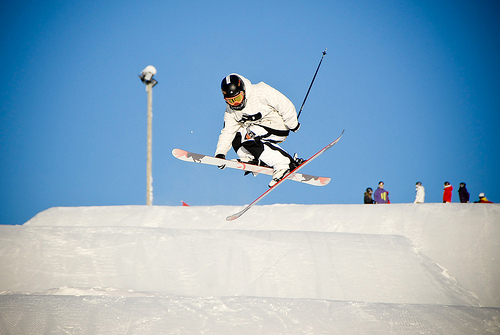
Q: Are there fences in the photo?
A: No, there are no fences.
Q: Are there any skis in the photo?
A: Yes, there are skis.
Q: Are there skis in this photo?
A: Yes, there are skis.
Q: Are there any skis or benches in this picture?
A: Yes, there are skis.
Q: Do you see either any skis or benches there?
A: Yes, there are skis.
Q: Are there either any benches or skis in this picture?
A: Yes, there are skis.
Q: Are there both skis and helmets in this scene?
A: Yes, there are both skis and a helmet.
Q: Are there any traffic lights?
A: No, there are no traffic lights.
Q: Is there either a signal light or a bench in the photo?
A: No, there are no traffic lights or benches.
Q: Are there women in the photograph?
A: No, there are no women.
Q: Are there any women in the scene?
A: No, there are no women.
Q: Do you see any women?
A: No, there are no women.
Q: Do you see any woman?
A: No, there are no women.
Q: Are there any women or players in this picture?
A: No, there are no women or players.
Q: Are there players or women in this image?
A: No, there are no women or players.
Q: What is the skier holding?
A: The skier is holding the skis.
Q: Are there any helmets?
A: Yes, there is a helmet.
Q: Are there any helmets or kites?
A: Yes, there is a helmet.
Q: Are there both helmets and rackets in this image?
A: No, there is a helmet but no rackets.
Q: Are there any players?
A: No, there are no players.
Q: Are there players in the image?
A: No, there are no players.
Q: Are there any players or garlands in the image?
A: No, there are no players or garlands.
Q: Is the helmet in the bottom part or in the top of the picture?
A: The helmet is in the top of the image.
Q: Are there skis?
A: Yes, there are skis.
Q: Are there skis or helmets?
A: Yes, there are skis.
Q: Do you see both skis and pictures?
A: No, there are skis but no pictures.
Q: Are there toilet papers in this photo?
A: No, there are no toilet papers.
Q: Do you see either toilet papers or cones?
A: No, there are no toilet papers or cones.